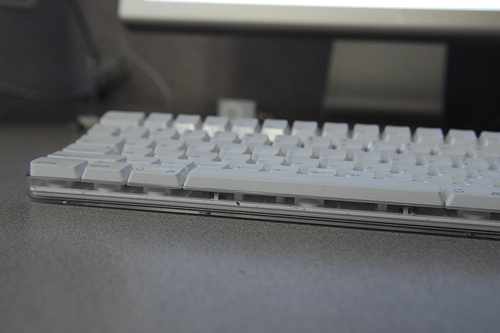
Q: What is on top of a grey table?
A: White computer keyboard.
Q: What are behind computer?
A: Wires Blurry.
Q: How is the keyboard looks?
A: White.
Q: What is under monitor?
A: White keyboard.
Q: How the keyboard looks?
A: Good.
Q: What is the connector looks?
A: Metal.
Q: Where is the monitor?
A: Behind the keyboard.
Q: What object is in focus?
A: Keyboard.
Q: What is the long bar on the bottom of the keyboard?
A: Space bar.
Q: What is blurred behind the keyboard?
A: Monitor.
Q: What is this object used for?
A: To type.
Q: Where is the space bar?
A: Bottom row of keyboard.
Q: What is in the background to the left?
A: Wires.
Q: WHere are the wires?
A: Left background.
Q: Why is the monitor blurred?
A: Focus is on keyboard.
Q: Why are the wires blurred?
A: Focus is on the keyboard.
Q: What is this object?
A: A keyboard.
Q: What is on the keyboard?
A: Keys.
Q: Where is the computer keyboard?
A: On a desk.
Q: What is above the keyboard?
A: The bottom edge of a monitor.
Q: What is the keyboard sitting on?
A: A table.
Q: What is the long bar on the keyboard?
A: A spacebar.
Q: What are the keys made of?
A: Plastic.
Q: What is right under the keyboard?
A: A gray surface.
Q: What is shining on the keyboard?
A: Light.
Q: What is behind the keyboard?
A: The monitor stand.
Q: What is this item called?
A: Keyboard.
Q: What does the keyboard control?
A: Computer.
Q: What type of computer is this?
A: Desktop.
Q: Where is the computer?
A: Desk.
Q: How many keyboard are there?
A: 1.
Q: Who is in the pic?
A: No one.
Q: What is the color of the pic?
A: Black and white.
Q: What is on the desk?
A: Keyboard.